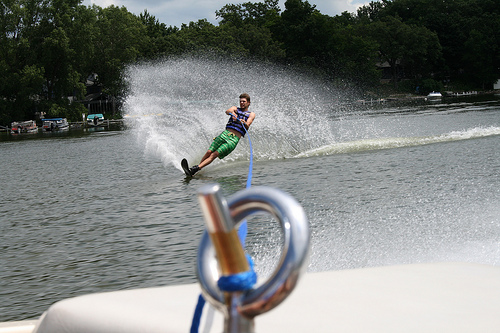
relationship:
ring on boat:
[192, 179, 312, 320] [2, 261, 499, 332]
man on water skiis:
[178, 93, 258, 182] [177, 155, 197, 180]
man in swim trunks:
[178, 93, 258, 182] [205, 127, 239, 161]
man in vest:
[178, 93, 258, 182] [226, 105, 252, 137]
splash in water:
[113, 49, 390, 174] [1, 96, 500, 321]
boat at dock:
[83, 110, 107, 128] [0, 115, 124, 134]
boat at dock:
[39, 114, 71, 133] [0, 115, 124, 134]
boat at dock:
[7, 115, 41, 138] [0, 115, 124, 134]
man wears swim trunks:
[178, 93, 258, 182] [205, 127, 239, 161]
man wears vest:
[178, 93, 258, 182] [226, 105, 252, 137]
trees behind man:
[0, 0, 498, 124] [178, 93, 258, 182]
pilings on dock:
[79, 110, 89, 125] [0, 115, 124, 134]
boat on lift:
[83, 110, 107, 128] [80, 106, 112, 134]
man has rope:
[178, 93, 258, 182] [188, 112, 259, 332]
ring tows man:
[192, 179, 312, 320] [178, 93, 258, 182]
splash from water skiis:
[113, 49, 390, 174] [177, 155, 197, 180]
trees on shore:
[0, 0, 498, 124] [0, 88, 499, 128]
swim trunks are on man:
[205, 127, 239, 161] [178, 93, 258, 182]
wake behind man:
[293, 124, 498, 157] [178, 93, 258, 182]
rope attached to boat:
[188, 112, 259, 332] [2, 261, 499, 332]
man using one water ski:
[178, 93, 258, 182] [177, 155, 197, 180]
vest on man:
[226, 105, 252, 137] [178, 93, 258, 182]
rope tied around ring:
[188, 112, 259, 332] [192, 179, 312, 320]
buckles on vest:
[234, 108, 246, 133] [226, 105, 252, 137]